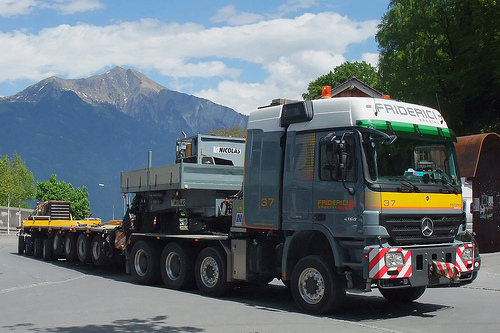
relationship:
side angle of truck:
[246, 95, 371, 316] [18, 95, 480, 303]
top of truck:
[248, 97, 451, 137] [18, 95, 480, 303]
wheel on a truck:
[287, 249, 347, 319] [71, 109, 454, 306]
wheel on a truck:
[192, 243, 229, 295] [16, 98, 485, 308]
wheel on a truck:
[126, 236, 158, 285] [16, 98, 485, 308]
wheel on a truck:
[86, 236, 116, 280] [16, 98, 485, 308]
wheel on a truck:
[73, 235, 90, 270] [16, 98, 485, 308]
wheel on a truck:
[60, 230, 77, 265] [16, 98, 485, 308]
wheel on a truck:
[89, 235, 109, 266] [16, 98, 485, 308]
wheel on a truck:
[157, 240, 192, 288] [16, 98, 485, 308]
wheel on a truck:
[288, 253, 345, 315] [16, 98, 485, 308]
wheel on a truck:
[48, 231, 63, 256] [16, 98, 485, 308]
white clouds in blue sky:
[5, 19, 361, 72] [4, 4, 401, 111]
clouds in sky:
[150, 11, 386, 70] [135, 41, 326, 93]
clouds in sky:
[0, 19, 381, 89] [0, 0, 394, 116]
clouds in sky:
[10, 25, 370, 62] [0, 0, 394, 116]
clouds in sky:
[3, 1, 390, 116] [0, 0, 394, 116]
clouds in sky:
[226, 27, 308, 77] [3, 5, 379, 76]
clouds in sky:
[0, 0, 380, 114] [0, 0, 394, 116]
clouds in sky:
[162, 62, 239, 77] [0, 0, 394, 116]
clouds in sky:
[238, 17, 346, 50] [0, 0, 394, 116]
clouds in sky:
[8, 4, 338, 85] [0, 0, 394, 116]